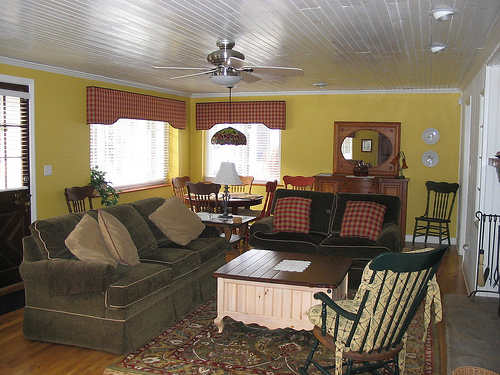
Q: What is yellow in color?
A: Walls.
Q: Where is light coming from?
A: Windows.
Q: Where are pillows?
A: On couches.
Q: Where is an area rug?
A: On the floor.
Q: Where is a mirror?
A: On the wall.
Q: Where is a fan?
A: On the ceiling.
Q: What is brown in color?
A: Couch on left.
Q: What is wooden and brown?
A: The floor.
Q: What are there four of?
A: Chairs.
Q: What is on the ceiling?
A: A fan.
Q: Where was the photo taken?
A: In a room.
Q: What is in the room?
A: Rocking chair.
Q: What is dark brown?
A: Couch pillows.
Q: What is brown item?
A: Couch.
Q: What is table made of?
A: Wood.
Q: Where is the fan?
A: On ceiling.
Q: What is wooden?
A: Table.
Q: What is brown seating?
A: Couch.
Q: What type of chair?
A: Rocking.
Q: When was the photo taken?
A: Daytime.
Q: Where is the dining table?
A: Corner.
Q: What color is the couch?
A: Brown.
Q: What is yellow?
A: Walls.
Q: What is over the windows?
A: Blinds.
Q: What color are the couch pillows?
A: Tan.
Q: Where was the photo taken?
A: In a living room.